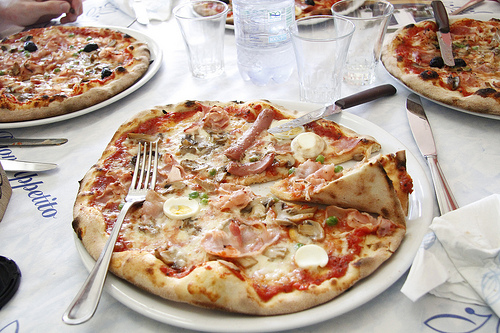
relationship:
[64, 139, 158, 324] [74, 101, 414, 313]
fork laying on pizza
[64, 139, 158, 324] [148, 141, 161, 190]
fork has prong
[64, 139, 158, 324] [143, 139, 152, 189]
fork has prong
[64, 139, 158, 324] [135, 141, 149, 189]
fork has prong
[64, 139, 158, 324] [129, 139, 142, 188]
fork has prong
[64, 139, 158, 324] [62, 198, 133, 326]
fork has handle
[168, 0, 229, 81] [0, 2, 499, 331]
glass sitting on table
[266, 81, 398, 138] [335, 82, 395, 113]
knife has handle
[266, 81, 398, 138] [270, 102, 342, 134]
knife has blade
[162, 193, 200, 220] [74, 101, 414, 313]
mushroom on pizza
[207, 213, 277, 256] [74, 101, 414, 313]
bacon on pizza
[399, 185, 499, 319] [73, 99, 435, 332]
napkin on side of dish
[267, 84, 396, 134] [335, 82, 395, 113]
knife has handle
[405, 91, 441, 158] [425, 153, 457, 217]
knife has handle